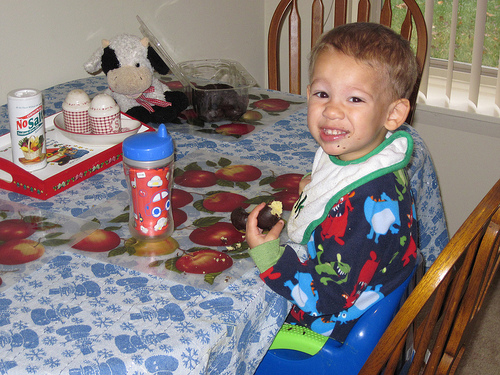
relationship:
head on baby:
[283, 20, 428, 160] [245, 28, 447, 305]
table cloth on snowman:
[0, 70, 449, 373] [28, 295, 87, 335]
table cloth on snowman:
[0, 70, 451, 374] [29, 301, 83, 328]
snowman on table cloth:
[0, 327, 40, 351] [0, 70, 449, 373]